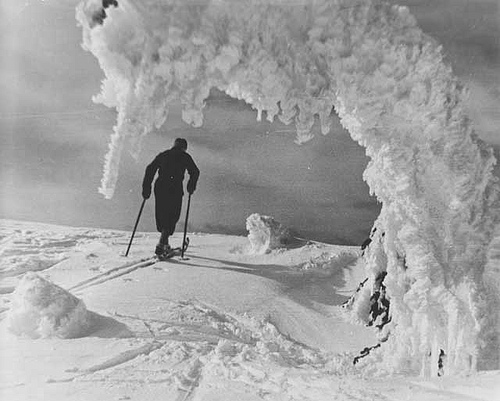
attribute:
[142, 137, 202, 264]
man — skiing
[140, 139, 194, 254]
man — skiing, in all black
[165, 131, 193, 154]
head — man's, the back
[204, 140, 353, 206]
sky — dark gray